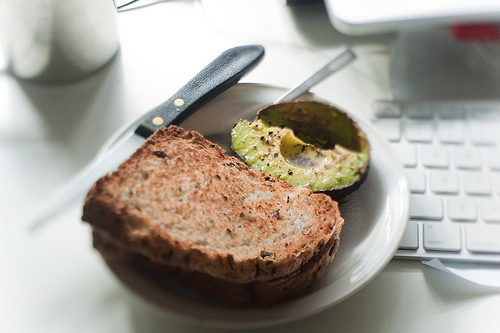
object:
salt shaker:
[0, 0, 123, 86]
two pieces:
[80, 123, 346, 309]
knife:
[21, 44, 266, 238]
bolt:
[152, 116, 165, 126]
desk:
[1, 2, 498, 332]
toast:
[95, 82, 411, 327]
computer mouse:
[0, 0, 121, 88]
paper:
[419, 258, 500, 288]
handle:
[227, 48, 357, 139]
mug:
[0, 1, 120, 85]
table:
[0, 0, 500, 333]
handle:
[134, 44, 267, 142]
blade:
[23, 132, 147, 234]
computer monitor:
[283, 0, 500, 38]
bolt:
[173, 97, 187, 107]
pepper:
[250, 123, 277, 160]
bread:
[77, 124, 343, 305]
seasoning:
[153, 150, 217, 230]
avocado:
[231, 101, 371, 200]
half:
[231, 99, 372, 195]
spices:
[258, 126, 278, 161]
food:
[80, 98, 372, 311]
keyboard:
[362, 19, 500, 267]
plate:
[86, 84, 408, 329]